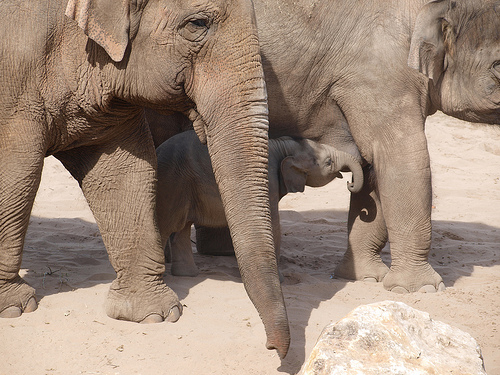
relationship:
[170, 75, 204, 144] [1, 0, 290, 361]
mouth of elephant